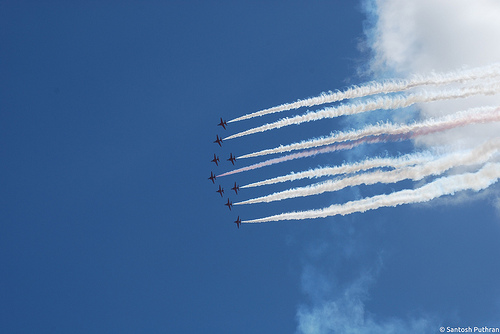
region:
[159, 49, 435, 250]
photo taken of airplanes in an air show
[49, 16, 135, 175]
clear blue sky with no clouds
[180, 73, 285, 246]
9 airplanes flying together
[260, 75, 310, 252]
smoke coming from back of airplanes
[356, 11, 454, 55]
clouds of smoke from planes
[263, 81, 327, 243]
smoke in a line before it becomes a cloud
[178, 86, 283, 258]
planes flying to the left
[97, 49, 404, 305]
photo taken from an angle below the planes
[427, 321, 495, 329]
watermark of photographer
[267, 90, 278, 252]
7 smoke lines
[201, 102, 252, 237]
some planes flying in formation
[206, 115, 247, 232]
a few fighter jets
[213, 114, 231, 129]
a distant fighter jet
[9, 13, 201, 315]
a clear blue sky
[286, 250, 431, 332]
a few thin clouds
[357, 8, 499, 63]
a thick white cloud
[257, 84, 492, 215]
a few lines of jet smoke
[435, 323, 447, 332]
a white copyright sign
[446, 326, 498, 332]
The photographers name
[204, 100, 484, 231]
a live air show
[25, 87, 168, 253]
cloudless portion of sky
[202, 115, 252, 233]
nine jets are flying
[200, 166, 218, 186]
jet leads other planes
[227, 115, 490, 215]
tail smoke from jets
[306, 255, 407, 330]
fluffy white clouds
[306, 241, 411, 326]
clouds in the sky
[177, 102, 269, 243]
planes all flying in same direction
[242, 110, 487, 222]
trail of smoke left by planes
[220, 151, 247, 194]
two jets are in the back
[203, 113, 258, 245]
jets fly in a v pattern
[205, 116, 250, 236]
airplanes in the sky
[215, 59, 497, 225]
contrails behind the planes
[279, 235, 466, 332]
a puff of white cloud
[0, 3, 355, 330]
the sky is a clear dark blue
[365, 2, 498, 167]
a large cloud in the sky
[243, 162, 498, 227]
this contrail is white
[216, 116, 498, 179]
this contrail is slightly pink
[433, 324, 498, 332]
a copyright label in the corner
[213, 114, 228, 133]
this plane is on top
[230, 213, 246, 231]
this plane is on the bottom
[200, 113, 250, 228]
9 fighter jets fly in formation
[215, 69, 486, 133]
jet leaves a trail of smoke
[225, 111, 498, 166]
jet leaves a trail of smoke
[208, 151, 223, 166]
jet is one of of only two in picture not leaving a trail of smoke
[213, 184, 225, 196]
jet is one of of only two in picture not leaving a trail of smoke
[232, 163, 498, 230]
jet is leaving a trail of smoke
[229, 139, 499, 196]
jet is leaving a trail of smoke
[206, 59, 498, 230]
jets moving quickly across the sky